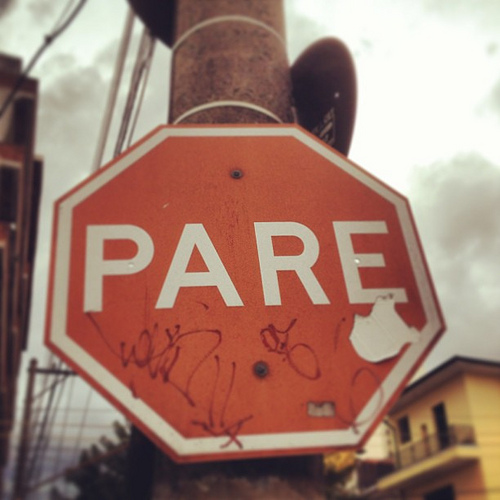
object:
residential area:
[1, 0, 499, 465]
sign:
[42, 125, 446, 465]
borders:
[64, 127, 171, 209]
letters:
[83, 221, 157, 313]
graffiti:
[122, 311, 343, 407]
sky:
[1, 0, 500, 449]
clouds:
[395, 148, 499, 273]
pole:
[171, 2, 299, 123]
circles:
[171, 14, 289, 50]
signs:
[127, 0, 179, 52]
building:
[373, 355, 499, 499]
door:
[428, 400, 453, 452]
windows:
[394, 414, 413, 446]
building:
[0, 52, 48, 460]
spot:
[346, 295, 422, 365]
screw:
[227, 165, 246, 185]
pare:
[80, 217, 407, 313]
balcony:
[375, 422, 478, 494]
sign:
[288, 32, 361, 155]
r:
[252, 221, 331, 307]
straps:
[170, 98, 284, 126]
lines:
[85, 0, 136, 175]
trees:
[102, 421, 128, 496]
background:
[0, 0, 499, 498]